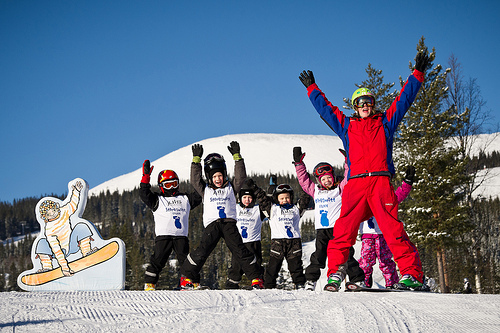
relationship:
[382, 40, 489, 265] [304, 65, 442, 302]
tree behind skater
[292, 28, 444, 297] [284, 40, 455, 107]
teacher has h hands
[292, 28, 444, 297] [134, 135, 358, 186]
teacher has h hands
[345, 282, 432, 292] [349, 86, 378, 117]
snowboarder on head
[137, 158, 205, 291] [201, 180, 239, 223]
child wearing shirt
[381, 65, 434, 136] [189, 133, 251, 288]
arm up of a child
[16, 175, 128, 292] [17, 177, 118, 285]
snowboarder sign with a picture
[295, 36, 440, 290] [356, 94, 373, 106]
adult wearing goggles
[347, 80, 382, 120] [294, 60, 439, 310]
head of skater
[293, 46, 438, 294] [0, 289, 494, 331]
snowboarder on top of a slope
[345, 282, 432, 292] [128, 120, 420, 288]
snowboarder in a class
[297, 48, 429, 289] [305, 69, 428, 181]
adult wearing a coat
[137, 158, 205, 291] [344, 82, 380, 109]
child wearing helmet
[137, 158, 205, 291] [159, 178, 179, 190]
child wearing snow glasses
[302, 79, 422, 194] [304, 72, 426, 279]
child wearing skisuit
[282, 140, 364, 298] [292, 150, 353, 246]
child wearing coat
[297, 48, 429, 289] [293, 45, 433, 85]
adult wearing gloves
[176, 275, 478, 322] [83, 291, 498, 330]
tracks in snow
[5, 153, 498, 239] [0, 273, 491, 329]
trees on mountainside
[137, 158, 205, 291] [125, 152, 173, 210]
child has arm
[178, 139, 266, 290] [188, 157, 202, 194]
child has arm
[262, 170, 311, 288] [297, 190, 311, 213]
child has arm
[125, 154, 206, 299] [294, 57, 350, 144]
child has arm